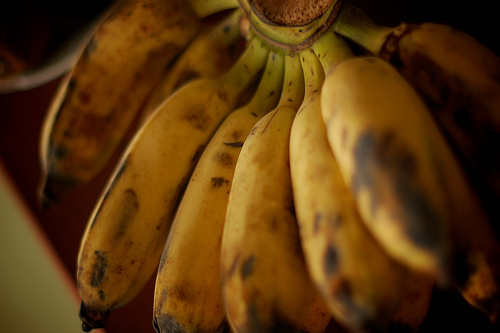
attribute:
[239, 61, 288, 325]
banana — yellow, over ripe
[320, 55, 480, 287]
banana — over ripe, yellow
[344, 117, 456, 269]
spot — black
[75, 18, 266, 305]
banana — small, yellow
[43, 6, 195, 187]
banana — yellow, small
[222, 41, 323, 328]
banana — small, yellow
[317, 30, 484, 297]
banana — small, yellow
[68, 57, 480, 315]
bananas — small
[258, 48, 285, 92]
banana stem — green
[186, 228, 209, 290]
peel — yellow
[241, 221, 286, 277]
peel — yellow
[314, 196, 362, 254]
peel — yellow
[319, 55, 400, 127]
peel — yellow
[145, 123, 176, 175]
peel — yellow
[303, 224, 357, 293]
spot — black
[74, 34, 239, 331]
banana — leftmost, unmolded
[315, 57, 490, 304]
banana — over ripe, yellow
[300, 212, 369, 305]
marks — black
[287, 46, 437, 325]
banana — yellow, small, second-from-right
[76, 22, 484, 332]
bananas — yellow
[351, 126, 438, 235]
spot — black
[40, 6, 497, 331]
bananas — old, rotting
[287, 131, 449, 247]
spot — black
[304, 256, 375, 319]
spot — black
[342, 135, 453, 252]
spot — black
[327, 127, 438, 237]
spot — black, blurred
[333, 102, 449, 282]
banana — rightmost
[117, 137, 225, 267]
portion — relatively unmolded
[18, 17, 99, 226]
section — blurred